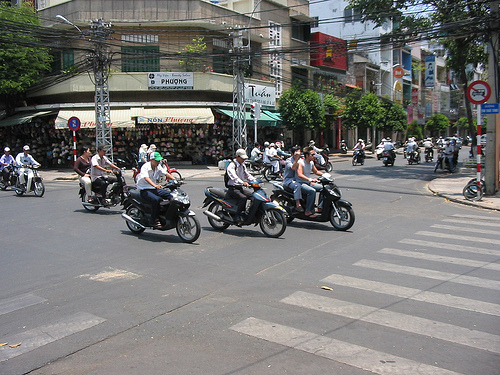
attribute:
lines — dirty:
[1, 210, 499, 374]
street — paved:
[0, 143, 499, 374]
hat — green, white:
[150, 151, 164, 162]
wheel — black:
[176, 213, 201, 243]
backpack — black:
[225, 160, 238, 189]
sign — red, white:
[468, 80, 492, 104]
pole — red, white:
[476, 105, 483, 195]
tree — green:
[344, 0, 500, 174]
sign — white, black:
[147, 72, 195, 94]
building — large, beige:
[0, 1, 310, 170]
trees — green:
[285, 80, 486, 150]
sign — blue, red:
[68, 117, 81, 131]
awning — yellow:
[138, 106, 214, 124]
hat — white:
[236, 149, 250, 160]